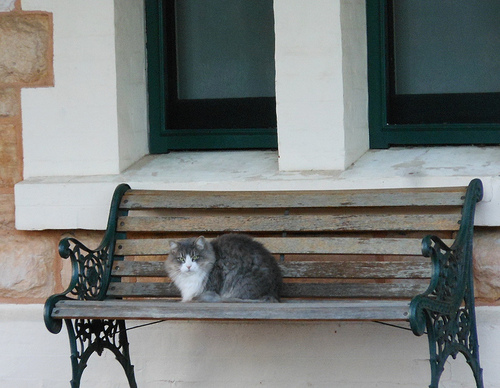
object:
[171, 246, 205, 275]
face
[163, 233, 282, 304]
cat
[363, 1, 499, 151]
window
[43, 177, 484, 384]
bench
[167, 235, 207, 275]
head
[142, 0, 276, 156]
window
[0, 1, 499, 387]
building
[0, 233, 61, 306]
block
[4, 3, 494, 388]
wall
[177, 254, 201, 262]
eye